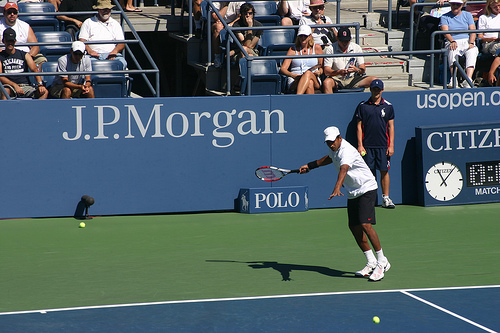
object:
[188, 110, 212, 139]
letter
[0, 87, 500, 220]
wall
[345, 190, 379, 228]
tennis shorts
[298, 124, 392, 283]
guy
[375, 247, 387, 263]
white socks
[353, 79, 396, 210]
guy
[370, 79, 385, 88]
hat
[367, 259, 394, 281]
shoe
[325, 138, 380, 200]
shirt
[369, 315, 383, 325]
tennis ball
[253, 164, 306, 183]
racket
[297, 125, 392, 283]
player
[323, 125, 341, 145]
cap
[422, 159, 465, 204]
clock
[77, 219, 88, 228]
ball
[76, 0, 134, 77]
man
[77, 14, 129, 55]
shirt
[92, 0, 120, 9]
hat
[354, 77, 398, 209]
man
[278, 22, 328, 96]
woman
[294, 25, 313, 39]
cap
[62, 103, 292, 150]
name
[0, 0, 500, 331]
background